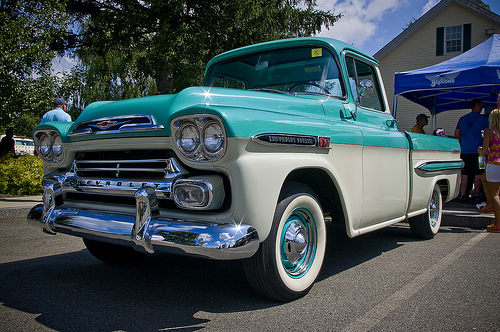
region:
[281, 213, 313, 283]
part of a wheel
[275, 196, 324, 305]
part of a wheel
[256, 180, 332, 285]
part of a wheel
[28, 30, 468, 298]
a fixed up old truck in the parking lot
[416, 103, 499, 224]
people standing around a tarp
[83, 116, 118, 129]
the logo of the car company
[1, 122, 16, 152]
a man standing under the tree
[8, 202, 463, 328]
the parking space the truck is parked in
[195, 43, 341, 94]
the front window of the car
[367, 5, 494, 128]
the building in the bathroom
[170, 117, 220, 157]
some headlights on the truck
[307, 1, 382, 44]
a white cloud in the sky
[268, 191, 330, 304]
a tire for the car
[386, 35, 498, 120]
the tent roof is blue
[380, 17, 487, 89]
the tent roof is blue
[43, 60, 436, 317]
a blue and cream vintage truck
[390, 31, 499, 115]
blue vendors tent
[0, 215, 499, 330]
black top paved parking lot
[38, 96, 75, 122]
man wearing a navy blue baseball cap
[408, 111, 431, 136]
man wearing an orange shirt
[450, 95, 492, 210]
tall man wearing a light blue shirt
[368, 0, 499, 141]
house with tan painted siding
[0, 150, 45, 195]
yellow green bush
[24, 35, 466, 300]
classic restored two-toned Chevrolet truck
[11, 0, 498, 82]
blue sky with white clouds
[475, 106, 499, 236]
woman in denim shorts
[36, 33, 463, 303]
a white and blue shining pick-up truck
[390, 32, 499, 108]
a blue canopy in a driveway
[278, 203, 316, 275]
blue and silver hubcap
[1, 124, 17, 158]
a person behind a bush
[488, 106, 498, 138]
a woman with blonde hair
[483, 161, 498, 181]
a woman wearing white shorts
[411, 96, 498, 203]
people standing beneath a canopy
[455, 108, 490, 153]
man wearing a blue shirt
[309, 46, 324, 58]
a yellow sticker on a windshield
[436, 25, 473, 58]
a white window with black shutters